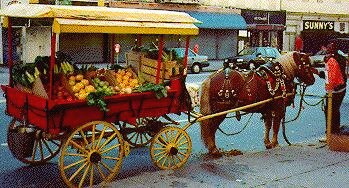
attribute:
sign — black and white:
[305, 18, 336, 31]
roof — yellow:
[3, 3, 195, 32]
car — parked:
[168, 45, 210, 73]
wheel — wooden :
[147, 123, 191, 173]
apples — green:
[82, 79, 114, 94]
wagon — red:
[3, 3, 208, 181]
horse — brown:
[166, 40, 337, 186]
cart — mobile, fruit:
[3, 2, 201, 180]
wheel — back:
[61, 120, 124, 185]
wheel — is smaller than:
[136, 122, 185, 176]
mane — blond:
[271, 49, 299, 82]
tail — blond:
[197, 76, 213, 148]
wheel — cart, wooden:
[64, 123, 124, 187]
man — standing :
[319, 35, 343, 139]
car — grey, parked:
[182, 45, 210, 68]